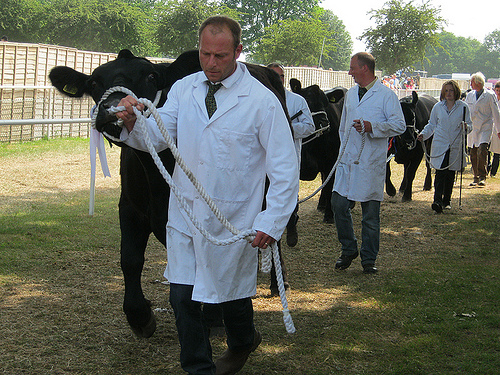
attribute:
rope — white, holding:
[129, 114, 235, 229]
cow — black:
[20, 38, 288, 360]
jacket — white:
[135, 56, 289, 285]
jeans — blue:
[320, 207, 402, 262]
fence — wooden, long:
[6, 25, 88, 120]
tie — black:
[185, 75, 240, 133]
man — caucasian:
[106, 90, 181, 149]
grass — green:
[22, 198, 118, 269]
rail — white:
[1, 107, 87, 141]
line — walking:
[58, 42, 452, 335]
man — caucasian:
[152, 251, 277, 374]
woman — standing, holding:
[401, 67, 466, 229]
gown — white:
[100, 54, 347, 323]